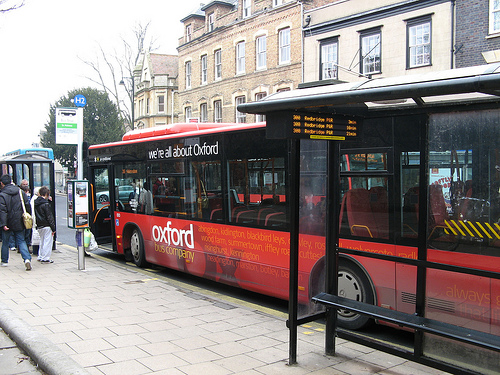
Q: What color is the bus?
A: Red, yellow, white and black.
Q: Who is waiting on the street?
A: Passengers.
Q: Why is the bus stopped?
A: To load and unload passengers.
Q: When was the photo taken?
A: Daytime.